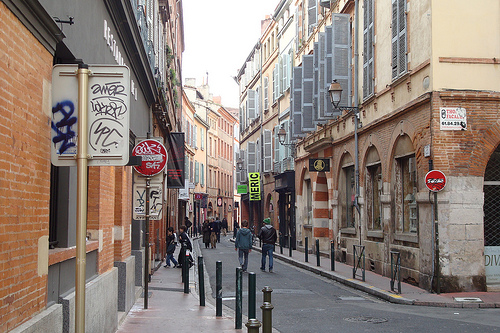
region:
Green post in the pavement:
[243, 268, 260, 330]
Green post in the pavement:
[227, 261, 242, 328]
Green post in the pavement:
[208, 254, 229, 326]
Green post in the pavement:
[193, 248, 211, 326]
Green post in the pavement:
[168, 246, 198, 298]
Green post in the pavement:
[323, 234, 338, 274]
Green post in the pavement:
[309, 236, 329, 276]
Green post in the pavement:
[296, 234, 313, 266]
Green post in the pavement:
[285, 229, 301, 274]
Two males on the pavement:
[231, 204, 291, 308]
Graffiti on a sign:
[52, 68, 128, 163]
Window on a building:
[388, 0, 411, 88]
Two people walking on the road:
[231, 212, 281, 279]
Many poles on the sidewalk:
[177, 249, 277, 330]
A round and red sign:
[127, 137, 169, 179]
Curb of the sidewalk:
[228, 235, 499, 312]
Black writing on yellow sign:
[246, 167, 265, 204]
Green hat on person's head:
[257, 211, 273, 229]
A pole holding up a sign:
[72, 66, 92, 330]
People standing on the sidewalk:
[162, 222, 193, 275]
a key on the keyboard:
[219, 218, 260, 269]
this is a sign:
[238, 165, 281, 216]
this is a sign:
[394, 158, 464, 213]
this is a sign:
[424, 88, 485, 155]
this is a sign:
[133, 139, 172, 178]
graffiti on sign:
[57, 75, 105, 141]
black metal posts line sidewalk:
[185, 250, 260, 318]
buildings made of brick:
[7, 8, 146, 300]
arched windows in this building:
[313, 131, 440, 273]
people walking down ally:
[196, 210, 283, 281]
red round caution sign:
[133, 130, 174, 197]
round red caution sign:
[409, 161, 444, 203]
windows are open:
[279, 30, 369, 131]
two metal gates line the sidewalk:
[348, 240, 403, 290]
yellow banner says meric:
[243, 165, 264, 214]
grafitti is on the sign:
[89, 78, 120, 159]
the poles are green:
[193, 253, 247, 327]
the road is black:
[282, 276, 317, 318]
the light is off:
[324, 77, 344, 104]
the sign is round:
[417, 155, 452, 204]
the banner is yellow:
[240, 162, 264, 204]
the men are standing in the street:
[219, 204, 283, 277]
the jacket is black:
[254, 222, 287, 248]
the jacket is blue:
[230, 225, 253, 251]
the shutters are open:
[275, 20, 349, 150]